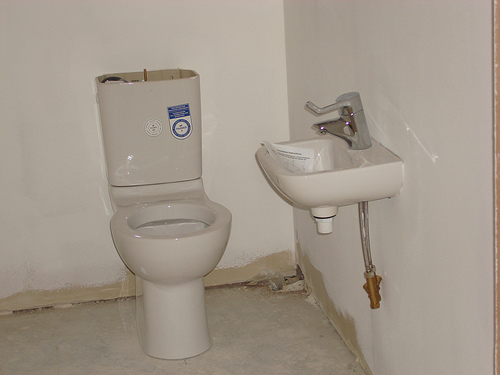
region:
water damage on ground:
[311, 298, 377, 340]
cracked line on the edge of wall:
[8, 296, 103, 323]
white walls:
[23, 105, 84, 212]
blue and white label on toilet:
[153, 98, 200, 153]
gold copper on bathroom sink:
[344, 271, 396, 316]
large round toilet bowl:
[116, 194, 247, 252]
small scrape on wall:
[395, 114, 449, 186]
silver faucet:
[283, 77, 394, 152]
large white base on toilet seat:
[118, 270, 256, 355]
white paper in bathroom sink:
[228, 109, 335, 202]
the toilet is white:
[87, 46, 241, 370]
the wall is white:
[17, 91, 78, 233]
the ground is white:
[36, 320, 124, 359]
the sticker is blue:
[160, 97, 197, 149]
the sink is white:
[246, 100, 412, 240]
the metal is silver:
[289, 78, 399, 162]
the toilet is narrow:
[75, 59, 247, 364]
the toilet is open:
[90, 61, 247, 362]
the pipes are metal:
[345, 206, 410, 321]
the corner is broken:
[245, 231, 340, 321]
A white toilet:
[92, 59, 232, 362]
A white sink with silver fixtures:
[254, 90, 405, 237]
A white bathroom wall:
[207, 26, 252, 95]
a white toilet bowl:
[108, 193, 233, 285]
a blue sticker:
[166, 100, 195, 137]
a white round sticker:
[142, 118, 164, 138]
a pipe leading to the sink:
[358, 199, 383, 308]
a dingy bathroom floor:
[239, 323, 307, 359]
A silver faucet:
[304, 88, 374, 150]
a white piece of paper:
[262, 138, 317, 177]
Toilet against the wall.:
[75, 45, 264, 359]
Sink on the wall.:
[234, 87, 467, 304]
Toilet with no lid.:
[101, 55, 272, 367]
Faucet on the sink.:
[311, 88, 421, 153]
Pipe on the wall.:
[345, 215, 402, 336]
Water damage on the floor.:
[230, 218, 359, 373]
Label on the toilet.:
[160, 95, 199, 144]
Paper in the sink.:
[260, 130, 360, 217]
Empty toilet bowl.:
[105, 202, 237, 278]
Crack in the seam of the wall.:
[12, 270, 319, 364]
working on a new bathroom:
[33, 39, 422, 353]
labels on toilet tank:
[129, 96, 209, 151]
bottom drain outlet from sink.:
[307, 208, 352, 250]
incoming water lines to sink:
[341, 206, 396, 319]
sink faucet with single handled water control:
[276, 83, 388, 153]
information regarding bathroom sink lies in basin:
[256, 127, 334, 182]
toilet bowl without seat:
[103, 175, 235, 280]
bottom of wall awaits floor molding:
[248, 245, 403, 373]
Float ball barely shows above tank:
[83, 48, 232, 88]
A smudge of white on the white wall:
[384, 92, 454, 188]